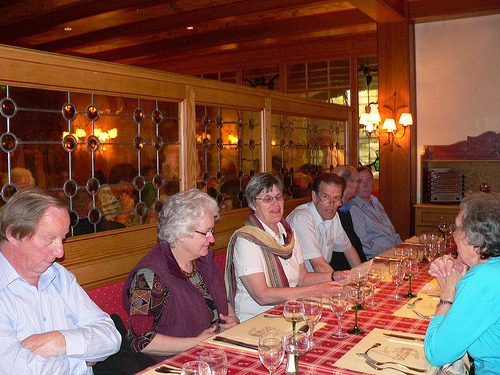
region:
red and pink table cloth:
[117, 230, 488, 373]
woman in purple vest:
[122, 188, 242, 353]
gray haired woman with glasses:
[117, 188, 240, 358]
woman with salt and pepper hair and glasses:
[220, 167, 357, 322]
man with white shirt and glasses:
[283, 172, 362, 287]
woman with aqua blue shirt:
[415, 191, 499, 373]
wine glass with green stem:
[397, 257, 420, 302]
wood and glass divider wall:
[3, 44, 358, 296]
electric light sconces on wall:
[360, 110, 411, 148]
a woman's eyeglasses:
[191, 226, 216, 237]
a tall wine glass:
[251, 317, 285, 374]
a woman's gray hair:
[155, 185, 221, 249]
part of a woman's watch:
[435, 295, 451, 307]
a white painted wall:
[414, 11, 497, 127]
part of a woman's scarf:
[222, 214, 297, 303]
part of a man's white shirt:
[282, 200, 351, 278]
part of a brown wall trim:
[373, 18, 413, 113]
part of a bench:
[76, 260, 129, 314]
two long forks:
[357, 347, 427, 374]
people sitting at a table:
[6, 161, 498, 367]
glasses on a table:
[291, 294, 331, 356]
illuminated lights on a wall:
[354, 103, 423, 147]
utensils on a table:
[358, 351, 419, 373]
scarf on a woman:
[228, 219, 300, 264]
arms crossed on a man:
[9, 323, 139, 371]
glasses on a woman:
[256, 190, 289, 210]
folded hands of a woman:
[426, 245, 463, 298]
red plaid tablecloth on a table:
[317, 324, 338, 351]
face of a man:
[311, 172, 350, 219]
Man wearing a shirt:
[0, 243, 124, 373]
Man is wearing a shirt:
[0, 250, 125, 373]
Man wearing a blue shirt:
[0, 242, 126, 373]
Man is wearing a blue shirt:
[0, 242, 124, 372]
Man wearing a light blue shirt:
[2, 247, 127, 372]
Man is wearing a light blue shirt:
[2, 246, 122, 373]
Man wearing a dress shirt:
[1, 247, 128, 373]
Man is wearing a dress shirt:
[1, 243, 129, 372]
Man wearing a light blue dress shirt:
[0, 246, 127, 373]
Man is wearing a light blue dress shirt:
[0, 247, 127, 373]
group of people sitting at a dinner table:
[2, 163, 498, 372]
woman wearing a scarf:
[221, 170, 354, 324]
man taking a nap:
[1, 187, 123, 374]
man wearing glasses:
[283, 172, 363, 274]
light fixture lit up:
[359, 105, 413, 152]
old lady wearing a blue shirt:
[424, 188, 499, 374]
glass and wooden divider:
[1, 73, 359, 288]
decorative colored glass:
[0, 80, 350, 244]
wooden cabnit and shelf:
[413, 130, 498, 235]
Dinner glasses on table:
[177, 221, 457, 374]